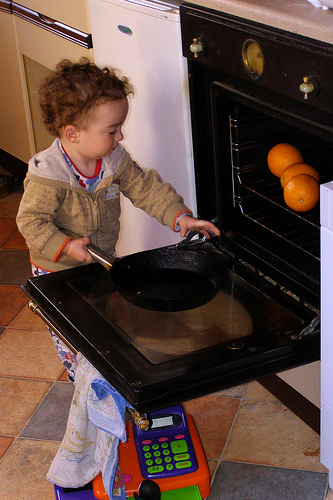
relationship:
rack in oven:
[239, 179, 324, 252] [221, 97, 284, 188]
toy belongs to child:
[97, 402, 217, 499] [16, 51, 220, 392]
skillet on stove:
[104, 227, 231, 312] [36, 103, 329, 402]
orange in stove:
[284, 173, 321, 213] [16, 1, 331, 419]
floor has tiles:
[1, 164, 327, 497] [4, 296, 57, 499]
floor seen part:
[1, 164, 327, 497] [253, 404, 283, 443]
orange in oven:
[280, 162, 319, 189] [196, 92, 309, 278]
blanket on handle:
[45, 351, 134, 498] [25, 299, 152, 430]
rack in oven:
[230, 166, 332, 235] [175, 2, 332, 306]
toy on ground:
[93, 402, 212, 500] [0, 170, 331, 496]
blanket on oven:
[45, 351, 134, 499] [26, 30, 331, 428]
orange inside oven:
[284, 173, 321, 213] [25, 10, 325, 414]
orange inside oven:
[280, 162, 319, 189] [25, 10, 325, 414]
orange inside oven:
[262, 138, 301, 176] [25, 10, 325, 414]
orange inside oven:
[279, 152, 301, 178] [25, 10, 325, 414]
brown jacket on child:
[15, 137, 192, 272] [16, 51, 220, 392]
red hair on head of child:
[42, 59, 122, 101] [27, 61, 193, 247]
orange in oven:
[284, 173, 321, 213] [192, 66, 320, 265]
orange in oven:
[265, 140, 302, 177] [25, 10, 325, 414]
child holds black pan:
[18, 59, 224, 276] [87, 240, 229, 311]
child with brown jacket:
[15, 57, 221, 383] [38, 171, 118, 244]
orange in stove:
[266, 143, 303, 175] [16, 1, 331, 419]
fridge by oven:
[88, 1, 197, 256] [25, 10, 325, 414]